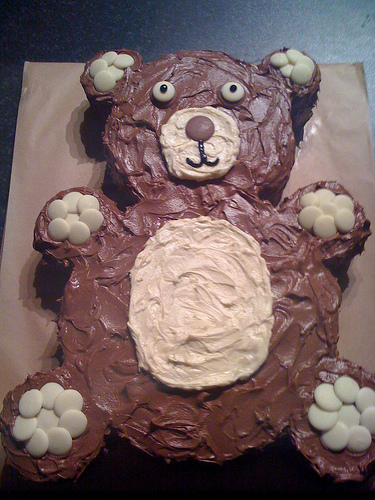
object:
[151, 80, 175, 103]
circular chip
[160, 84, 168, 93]
black bead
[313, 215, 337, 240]
chocolate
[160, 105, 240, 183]
snout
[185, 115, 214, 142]
nose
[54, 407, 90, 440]
chip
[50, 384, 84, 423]
chip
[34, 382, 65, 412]
chip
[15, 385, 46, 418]
chip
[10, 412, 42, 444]
chip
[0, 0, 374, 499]
table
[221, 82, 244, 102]
eye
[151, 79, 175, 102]
eye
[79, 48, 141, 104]
ear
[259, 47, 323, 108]
ear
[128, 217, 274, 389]
patch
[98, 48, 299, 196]
cake face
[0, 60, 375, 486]
board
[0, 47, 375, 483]
bear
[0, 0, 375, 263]
countertop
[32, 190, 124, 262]
paw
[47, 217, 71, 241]
pieces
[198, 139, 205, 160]
line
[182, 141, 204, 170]
frosting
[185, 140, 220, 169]
mouth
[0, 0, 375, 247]
surface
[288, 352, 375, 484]
bear's foot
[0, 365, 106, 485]
bear's foot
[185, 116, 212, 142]
chocolate